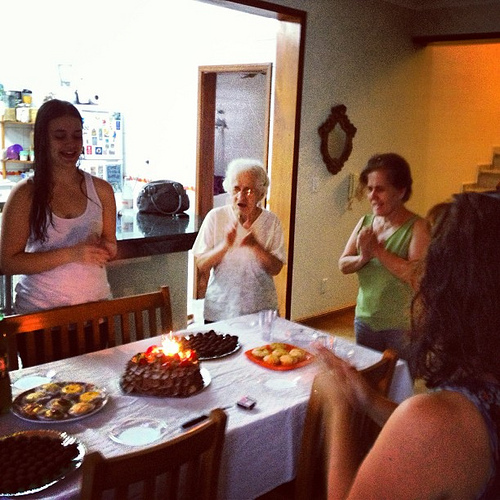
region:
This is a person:
[185, 123, 319, 350]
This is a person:
[340, 119, 451, 363]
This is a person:
[1, 79, 159, 339]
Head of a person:
[32, 82, 103, 192]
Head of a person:
[218, 139, 275, 231]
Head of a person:
[357, 131, 428, 236]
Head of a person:
[404, 183, 496, 358]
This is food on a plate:
[17, 371, 118, 448]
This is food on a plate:
[244, 318, 315, 376]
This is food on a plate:
[180, 309, 248, 370]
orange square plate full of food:
[245, 340, 312, 373]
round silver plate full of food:
[14, 380, 110, 422]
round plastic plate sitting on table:
[108, 418, 171, 443]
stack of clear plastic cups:
[258, 310, 277, 340]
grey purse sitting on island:
[136, 180, 189, 213]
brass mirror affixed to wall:
[319, 103, 358, 175]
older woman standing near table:
[195, 155, 288, 327]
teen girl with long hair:
[0, 97, 120, 368]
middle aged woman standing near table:
[334, 152, 431, 350]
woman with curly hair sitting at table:
[311, 191, 497, 493]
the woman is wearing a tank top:
[19, 160, 108, 307]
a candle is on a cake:
[156, 331, 186, 360]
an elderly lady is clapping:
[196, 163, 290, 316]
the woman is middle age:
[356, 204, 421, 330]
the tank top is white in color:
[20, 170, 105, 304]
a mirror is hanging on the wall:
[318, 104, 358, 180]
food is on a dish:
[244, 337, 312, 369]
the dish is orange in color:
[249, 335, 316, 372]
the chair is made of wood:
[83, 415, 228, 497]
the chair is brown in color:
[81, 413, 229, 498]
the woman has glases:
[196, 169, 306, 311]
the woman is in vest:
[7, 188, 122, 313]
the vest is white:
[34, 203, 122, 299]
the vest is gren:
[346, 224, 406, 332]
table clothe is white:
[228, 316, 338, 418]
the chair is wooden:
[85, 431, 251, 497]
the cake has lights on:
[116, 325, 198, 392]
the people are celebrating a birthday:
[9, 156, 474, 498]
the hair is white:
[214, 150, 267, 194]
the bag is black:
[136, 180, 193, 234]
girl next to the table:
[1, 99, 161, 279]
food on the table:
[18, 319, 315, 474]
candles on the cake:
[143, 332, 196, 374]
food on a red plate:
[249, 335, 314, 381]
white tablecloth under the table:
[216, 374, 283, 396]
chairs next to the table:
[13, 310, 164, 365]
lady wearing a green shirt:
[309, 141, 454, 313]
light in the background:
[415, 48, 497, 121]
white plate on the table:
[107, 400, 172, 459]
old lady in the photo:
[170, 153, 327, 313]